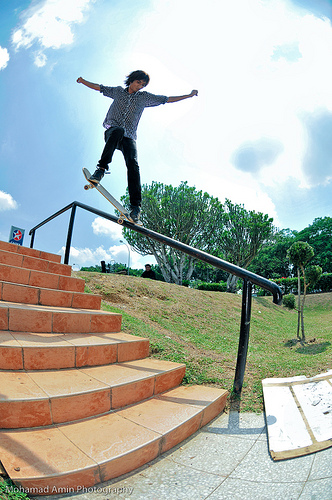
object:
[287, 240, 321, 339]
tree